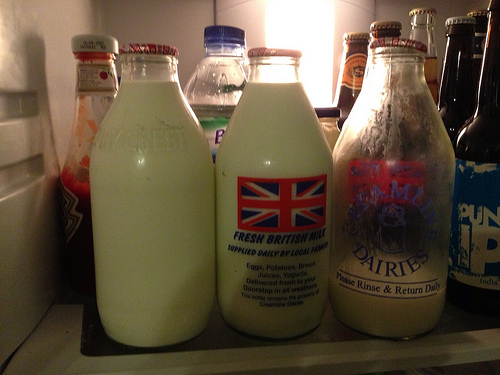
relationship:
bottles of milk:
[101, 38, 319, 311] [99, 43, 212, 313]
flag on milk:
[233, 173, 326, 230] [99, 43, 212, 313]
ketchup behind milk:
[57, 25, 93, 239] [99, 43, 212, 313]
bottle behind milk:
[437, 14, 475, 118] [99, 43, 212, 313]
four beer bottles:
[411, 7, 498, 119] [101, 38, 319, 311]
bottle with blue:
[437, 14, 475, 118] [201, 24, 250, 50]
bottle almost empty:
[437, 14, 475, 118] [334, 38, 446, 275]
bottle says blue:
[437, 14, 475, 118] [201, 24, 250, 50]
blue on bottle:
[201, 24, 250, 50] [437, 14, 475, 118]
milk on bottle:
[99, 43, 212, 313] [437, 14, 475, 118]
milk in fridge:
[99, 43, 212, 313] [2, 4, 492, 372]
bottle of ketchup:
[437, 14, 475, 118] [57, 25, 93, 239]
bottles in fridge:
[101, 38, 319, 311] [2, 4, 492, 372]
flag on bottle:
[233, 173, 326, 230] [437, 14, 475, 118]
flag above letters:
[233, 173, 326, 230] [240, 260, 321, 314]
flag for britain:
[233, 173, 326, 230] [266, 233, 309, 246]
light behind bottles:
[262, 4, 335, 46] [101, 38, 319, 311]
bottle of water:
[437, 14, 475, 118] [186, 24, 247, 126]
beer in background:
[413, 3, 498, 145] [15, 7, 496, 99]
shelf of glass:
[30, 338, 499, 369] [209, 328, 231, 354]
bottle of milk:
[437, 14, 475, 118] [99, 43, 212, 313]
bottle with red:
[437, 14, 475, 118] [139, 44, 161, 53]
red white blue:
[139, 44, 161, 53] [201, 24, 250, 50]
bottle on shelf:
[437, 14, 475, 118] [30, 338, 499, 369]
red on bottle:
[139, 44, 161, 53] [437, 14, 475, 118]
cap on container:
[199, 24, 247, 55] [183, 53, 238, 117]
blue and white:
[201, 24, 250, 50] [471, 227, 486, 252]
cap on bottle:
[199, 24, 247, 55] [437, 14, 475, 118]